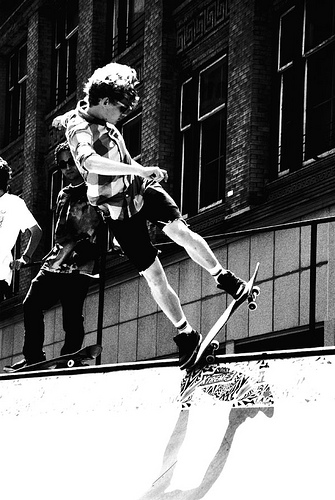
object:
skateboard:
[4, 342, 98, 370]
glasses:
[112, 97, 141, 119]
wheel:
[247, 301, 257, 312]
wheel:
[252, 285, 259, 294]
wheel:
[211, 337, 219, 348]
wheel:
[65, 358, 74, 368]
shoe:
[214, 266, 251, 304]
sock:
[207, 263, 226, 291]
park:
[0, 1, 334, 500]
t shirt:
[0, 191, 37, 289]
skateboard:
[184, 262, 262, 372]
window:
[179, 75, 198, 130]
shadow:
[134, 406, 275, 500]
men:
[61, 59, 249, 372]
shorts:
[112, 179, 183, 276]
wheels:
[209, 340, 220, 351]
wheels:
[205, 352, 216, 366]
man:
[0, 155, 43, 303]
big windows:
[302, 34, 334, 164]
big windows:
[197, 106, 227, 212]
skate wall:
[0, 346, 334, 498]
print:
[174, 351, 273, 412]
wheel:
[248, 301, 257, 310]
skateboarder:
[21, 142, 103, 370]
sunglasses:
[55, 158, 75, 171]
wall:
[0, 1, 334, 375]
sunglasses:
[117, 99, 139, 120]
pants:
[19, 269, 88, 364]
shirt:
[62, 99, 161, 225]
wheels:
[251, 283, 261, 297]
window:
[198, 55, 229, 120]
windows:
[182, 125, 202, 217]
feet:
[211, 270, 248, 302]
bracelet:
[21, 251, 30, 263]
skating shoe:
[168, 323, 200, 375]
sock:
[171, 315, 194, 340]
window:
[278, 1, 304, 68]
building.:
[0, 0, 334, 362]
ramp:
[0, 350, 333, 500]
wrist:
[129, 164, 144, 182]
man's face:
[104, 98, 128, 129]